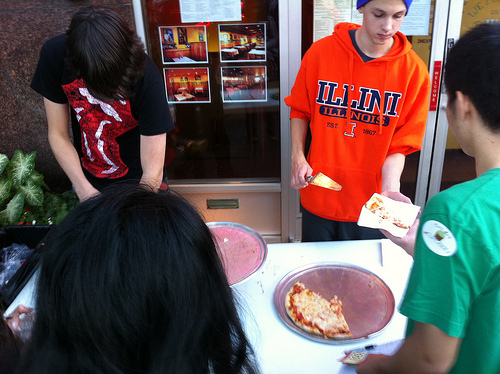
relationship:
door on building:
[288, 0, 450, 245] [1, 0, 499, 241]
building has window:
[3, 4, 498, 370] [130, 0, 282, 188]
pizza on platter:
[285, 279, 351, 336] [202, 218, 270, 290]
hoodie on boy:
[282, 21, 431, 223] [352, 19, 499, 373]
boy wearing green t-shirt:
[285, 1, 429, 241] [396, 165, 499, 374]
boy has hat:
[285, 1, 429, 241] [356, 0, 412, 17]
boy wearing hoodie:
[285, 1, 429, 241] [294, 35, 407, 181]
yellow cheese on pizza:
[294, 289, 346, 330] [282, 279, 352, 339]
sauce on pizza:
[284, 276, 352, 340] [283, 275, 354, 345]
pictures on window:
[149, 19, 270, 111] [138, 2, 285, 175]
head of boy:
[362, 0, 405, 46] [307, 19, 447, 159]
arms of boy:
[44, 98, 164, 190] [31, 8, 170, 202]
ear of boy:
[451, 89, 472, 127] [352, 14, 497, 372]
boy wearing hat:
[285, 1, 429, 241] [352, 0, 414, 10]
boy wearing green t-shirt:
[352, 19, 499, 373] [419, 206, 496, 365]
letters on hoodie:
[318, 80, 404, 121] [282, 21, 431, 223]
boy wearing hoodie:
[285, 1, 429, 241] [282, 21, 431, 223]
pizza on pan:
[285, 279, 351, 336] [274, 260, 396, 344]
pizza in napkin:
[362, 190, 413, 232] [356, 192, 421, 239]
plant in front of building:
[0, 142, 52, 222] [29, 18, 465, 367]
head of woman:
[39, 183, 253, 372] [17, 149, 261, 372]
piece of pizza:
[349, 185, 432, 237] [278, 275, 358, 340]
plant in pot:
[0, 142, 52, 222] [4, 199, 70, 253]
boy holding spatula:
[285, 1, 429, 241] [300, 171, 342, 191]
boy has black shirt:
[31, 8, 170, 202] [30, 32, 176, 189]